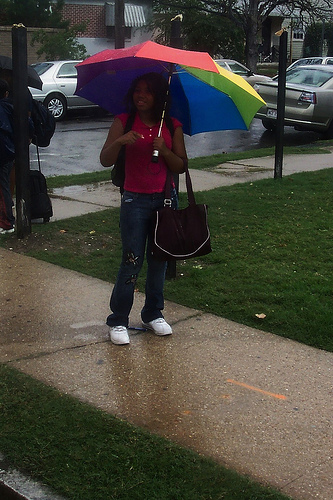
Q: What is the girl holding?
A: Umbrella.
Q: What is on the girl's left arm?
A: Bag.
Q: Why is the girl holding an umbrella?
A: Raining.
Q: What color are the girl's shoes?
A: White.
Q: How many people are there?
A: 2.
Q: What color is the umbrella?
A: Blue, red and yellow.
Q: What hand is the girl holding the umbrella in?
A: Left.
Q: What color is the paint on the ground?
A: Orange.